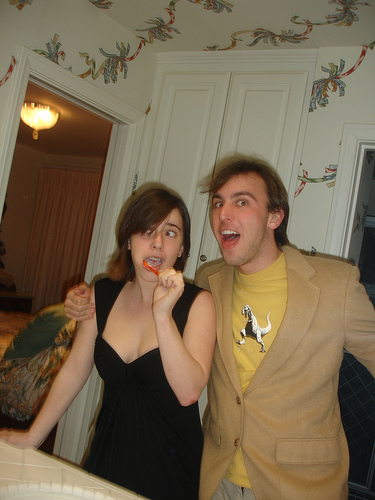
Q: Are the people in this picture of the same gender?
A: No, they are both male and female.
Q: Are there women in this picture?
A: Yes, there is a woman.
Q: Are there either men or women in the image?
A: Yes, there is a woman.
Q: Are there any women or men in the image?
A: Yes, there is a woman.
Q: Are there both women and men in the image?
A: Yes, there are both a woman and a man.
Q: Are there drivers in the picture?
A: No, there are no drivers.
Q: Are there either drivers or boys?
A: No, there are no drivers or boys.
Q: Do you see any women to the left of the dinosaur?
A: Yes, there is a woman to the left of the dinosaur.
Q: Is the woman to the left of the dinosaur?
A: Yes, the woman is to the left of the dinosaur.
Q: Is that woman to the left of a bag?
A: No, the woman is to the left of the dinosaur.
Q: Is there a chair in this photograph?
A: No, there are no chairs.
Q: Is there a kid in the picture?
A: No, there are no children.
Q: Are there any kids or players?
A: No, there are no kids or players.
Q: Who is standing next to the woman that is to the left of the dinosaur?
A: The man is standing next to the woman.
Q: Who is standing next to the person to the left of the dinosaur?
A: The man is standing next to the woman.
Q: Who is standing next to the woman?
A: The man is standing next to the woman.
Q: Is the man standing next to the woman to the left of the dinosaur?
A: Yes, the man is standing next to the woman.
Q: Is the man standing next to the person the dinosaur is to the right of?
A: Yes, the man is standing next to the woman.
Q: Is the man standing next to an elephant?
A: No, the man is standing next to the woman.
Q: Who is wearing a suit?
A: The man is wearing a suit.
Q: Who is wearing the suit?
A: The man is wearing a suit.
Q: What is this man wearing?
A: The man is wearing a suit.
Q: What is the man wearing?
A: The man is wearing a suit.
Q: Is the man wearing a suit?
A: Yes, the man is wearing a suit.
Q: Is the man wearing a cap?
A: No, the man is wearing a suit.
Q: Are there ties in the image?
A: No, there are no ties.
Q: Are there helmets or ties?
A: No, there are no ties or helmets.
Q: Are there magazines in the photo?
A: No, there are no magazines.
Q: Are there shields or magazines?
A: No, there are no magazines or shields.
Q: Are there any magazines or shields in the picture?
A: No, there are no magazines or shields.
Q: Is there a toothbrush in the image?
A: Yes, there is a toothbrush.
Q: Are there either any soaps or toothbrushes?
A: Yes, there is a toothbrush.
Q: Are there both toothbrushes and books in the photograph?
A: No, there is a toothbrush but no books.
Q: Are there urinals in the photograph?
A: No, there are no urinals.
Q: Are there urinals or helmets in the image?
A: No, there are no urinals or helmets.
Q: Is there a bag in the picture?
A: No, there are no bags.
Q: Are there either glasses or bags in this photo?
A: No, there are no bags or glasses.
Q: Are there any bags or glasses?
A: No, there are no bags or glasses.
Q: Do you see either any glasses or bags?
A: No, there are no bags or glasses.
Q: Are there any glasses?
A: No, there are no glasses.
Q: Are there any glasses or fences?
A: No, there are no glasses or fences.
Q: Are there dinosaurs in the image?
A: Yes, there is a dinosaur.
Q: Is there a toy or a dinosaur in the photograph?
A: Yes, there is a dinosaur.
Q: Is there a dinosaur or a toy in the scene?
A: Yes, there is a dinosaur.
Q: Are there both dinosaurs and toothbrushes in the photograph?
A: Yes, there are both a dinosaur and a toothbrush.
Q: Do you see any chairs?
A: No, there are no chairs.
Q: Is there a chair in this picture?
A: No, there are no chairs.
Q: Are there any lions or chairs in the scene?
A: No, there are no chairs or lions.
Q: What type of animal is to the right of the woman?
A: The animal is a dinosaur.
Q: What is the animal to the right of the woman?
A: The animal is a dinosaur.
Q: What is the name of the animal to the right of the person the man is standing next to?
A: The animal is a dinosaur.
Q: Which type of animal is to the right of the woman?
A: The animal is a dinosaur.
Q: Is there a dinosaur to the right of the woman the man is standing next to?
A: Yes, there is a dinosaur to the right of the woman.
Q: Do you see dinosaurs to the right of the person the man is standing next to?
A: Yes, there is a dinosaur to the right of the woman.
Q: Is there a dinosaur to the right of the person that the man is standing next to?
A: Yes, there is a dinosaur to the right of the woman.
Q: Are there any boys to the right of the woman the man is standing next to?
A: No, there is a dinosaur to the right of the woman.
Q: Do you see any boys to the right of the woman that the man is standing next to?
A: No, there is a dinosaur to the right of the woman.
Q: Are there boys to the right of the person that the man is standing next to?
A: No, there is a dinosaur to the right of the woman.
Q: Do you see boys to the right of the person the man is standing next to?
A: No, there is a dinosaur to the right of the woman.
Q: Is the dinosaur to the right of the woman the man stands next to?
A: Yes, the dinosaur is to the right of the woman.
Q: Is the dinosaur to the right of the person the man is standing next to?
A: Yes, the dinosaur is to the right of the woman.